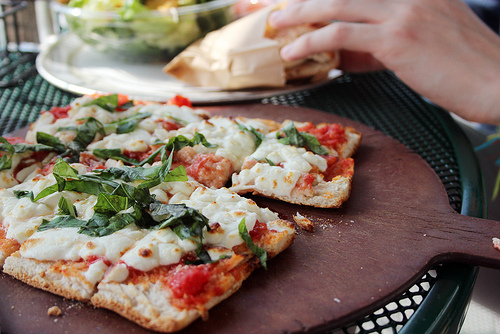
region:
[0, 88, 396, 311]
this is a pizza made with bread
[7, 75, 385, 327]
the bread is thin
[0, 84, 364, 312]
there are tomato chunks on the pizza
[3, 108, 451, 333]
the pizza is on a wooden tray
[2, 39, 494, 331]
the table is green and metal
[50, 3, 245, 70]
a salad in a bowl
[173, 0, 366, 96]
a sandwich in a paper wrapper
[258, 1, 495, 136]
a person's hand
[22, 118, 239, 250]
basil leaves on top of the pizza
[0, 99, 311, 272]
the cheese is white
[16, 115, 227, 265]
spinach on the pizza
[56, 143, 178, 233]
green fresh looking spinach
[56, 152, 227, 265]
green vegetable topping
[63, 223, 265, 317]
pizza with sauce and cheese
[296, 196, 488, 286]
brown wooden serving platter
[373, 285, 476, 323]
round black table with holes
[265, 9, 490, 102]
part of a persons hand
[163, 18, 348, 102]
hand is tooking brown bag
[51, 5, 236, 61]
bowl with greens in it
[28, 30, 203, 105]
large white dinner plate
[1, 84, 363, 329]
Individual flat bread pizza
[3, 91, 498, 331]
Pizza served on wooden pizza board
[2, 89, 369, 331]
Vegetarian style pizza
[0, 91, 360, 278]
sliced up lettuce top the pizza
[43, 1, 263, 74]
blurred out bowl of salad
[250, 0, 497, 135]
Hand grabbing a sandwich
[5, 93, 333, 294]
melted mozzarella cheese on top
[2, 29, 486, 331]
plate and board on green grated table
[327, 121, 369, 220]
crispy pizza edges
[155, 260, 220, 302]
chunks of tomatoes on pizza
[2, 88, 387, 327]
a pizza on a board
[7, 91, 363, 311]
a square pizza on a serving tray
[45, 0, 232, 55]
a bowl of a salad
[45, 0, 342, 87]
lunch on a plate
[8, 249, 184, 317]
crust on a pizza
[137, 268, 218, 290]
tomato on a pizza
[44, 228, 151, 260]
cheese on a pizza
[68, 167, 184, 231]
spinach on a pizza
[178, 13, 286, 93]
a brown paper bag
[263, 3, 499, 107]
a person's hand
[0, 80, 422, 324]
flat bread pizza with mozzarella cheese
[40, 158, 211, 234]
green leaves atop pizza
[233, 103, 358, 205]
pizza cut into rectangular slice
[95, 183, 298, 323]
rectangular slice of pizza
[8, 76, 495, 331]
dark wood board with pizza on it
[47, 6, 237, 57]
clear bowl with salad in it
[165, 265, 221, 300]
chunk of tomato on pizza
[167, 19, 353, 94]
brown paper bag on silver tray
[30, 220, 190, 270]
melted mozzarella cheese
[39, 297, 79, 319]
crumb laying beside pizza